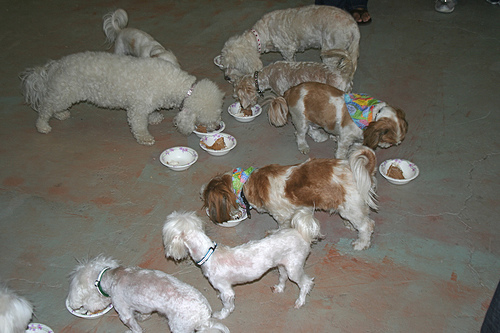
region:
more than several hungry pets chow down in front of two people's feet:
[0, 0, 497, 330]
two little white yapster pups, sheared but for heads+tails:
[60, 195, 330, 330]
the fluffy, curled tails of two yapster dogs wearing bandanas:
[260, 90, 385, 210]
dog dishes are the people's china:
[21, 96, 426, 328]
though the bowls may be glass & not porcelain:
[21, 90, 432, 330]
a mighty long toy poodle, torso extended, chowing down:
[13, 46, 233, 147]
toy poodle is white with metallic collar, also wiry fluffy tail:
[6, 41, 228, 158]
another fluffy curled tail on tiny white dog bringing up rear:
[91, 5, 136, 50]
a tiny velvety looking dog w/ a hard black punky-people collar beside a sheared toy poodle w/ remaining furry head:
[230, 43, 360, 118]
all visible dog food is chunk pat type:
[185, 98, 423, 185]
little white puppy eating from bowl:
[63, 251, 229, 332]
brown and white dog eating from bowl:
[199, 146, 391, 247]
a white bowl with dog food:
[377, 154, 422, 186]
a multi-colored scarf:
[341, 91, 381, 128]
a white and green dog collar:
[193, 239, 218, 267]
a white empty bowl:
[156, 143, 206, 171]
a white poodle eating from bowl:
[23, 50, 228, 146]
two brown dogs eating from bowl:
[211, 5, 363, 124]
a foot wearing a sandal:
[347, 0, 377, 26]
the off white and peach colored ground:
[12, 146, 151, 248]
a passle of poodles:
[15, 3, 452, 325]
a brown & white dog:
[182, 160, 397, 230]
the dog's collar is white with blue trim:
[196, 237, 226, 272]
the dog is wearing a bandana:
[227, 162, 260, 217]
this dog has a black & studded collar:
[249, 60, 269, 104]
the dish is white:
[146, 140, 206, 172]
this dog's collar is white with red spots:
[246, 22, 267, 53]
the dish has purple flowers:
[162, 139, 202, 181]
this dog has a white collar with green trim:
[94, 261, 116, 307]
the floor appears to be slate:
[34, 159, 142, 264]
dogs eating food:
[41, 11, 428, 331]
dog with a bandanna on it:
[240, 57, 492, 174]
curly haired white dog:
[27, 22, 229, 157]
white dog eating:
[64, 227, 193, 332]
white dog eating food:
[220, 54, 369, 103]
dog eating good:
[86, 10, 207, 76]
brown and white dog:
[212, 133, 397, 223]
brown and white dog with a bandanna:
[257, 63, 431, 168]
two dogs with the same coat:
[180, 66, 445, 248]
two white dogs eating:
[36, 229, 346, 311]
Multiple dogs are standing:
[32, 12, 397, 332]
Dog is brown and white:
[208, 153, 398, 255]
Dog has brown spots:
[198, 165, 391, 256]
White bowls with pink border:
[154, 127, 197, 174]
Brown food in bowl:
[373, 158, 435, 209]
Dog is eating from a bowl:
[27, 27, 225, 154]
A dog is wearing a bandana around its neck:
[278, 62, 422, 191]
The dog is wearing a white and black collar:
[158, 202, 270, 297]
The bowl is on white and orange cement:
[150, 141, 211, 196]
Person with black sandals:
[328, 5, 383, 40]